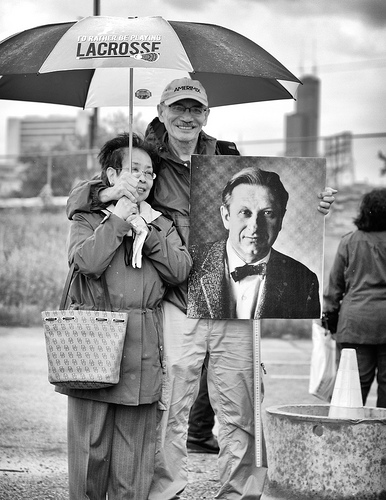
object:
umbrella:
[88, 20, 152, 31]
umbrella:
[208, 29, 255, 105]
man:
[157, 82, 209, 156]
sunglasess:
[171, 107, 204, 120]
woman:
[132, 148, 155, 204]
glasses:
[133, 167, 157, 179]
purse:
[41, 307, 124, 392]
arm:
[71, 211, 125, 283]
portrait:
[192, 152, 321, 322]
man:
[220, 171, 282, 266]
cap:
[156, 80, 211, 104]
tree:
[13, 141, 77, 153]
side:
[2, 101, 34, 323]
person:
[335, 186, 384, 351]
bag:
[309, 328, 336, 400]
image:
[0, 12, 384, 499]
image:
[219, 107, 280, 138]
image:
[273, 268, 306, 315]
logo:
[75, 35, 167, 62]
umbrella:
[0, 15, 271, 77]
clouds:
[368, 3, 384, 21]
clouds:
[342, 22, 358, 35]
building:
[300, 43, 323, 152]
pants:
[67, 407, 157, 499]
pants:
[163, 308, 188, 498]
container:
[268, 403, 386, 498]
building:
[6, 116, 85, 144]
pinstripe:
[77, 404, 78, 499]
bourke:
[78, 338, 83, 344]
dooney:
[75, 336, 82, 343]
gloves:
[124, 237, 134, 267]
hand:
[129, 217, 150, 231]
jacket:
[129, 229, 163, 402]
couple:
[88, 89, 208, 202]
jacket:
[155, 133, 171, 206]